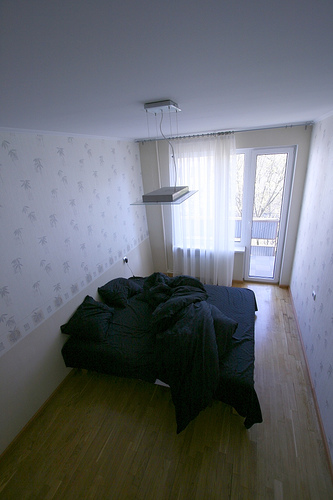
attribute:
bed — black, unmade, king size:
[62, 276, 263, 428]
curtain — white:
[168, 131, 236, 288]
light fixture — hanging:
[130, 98, 199, 206]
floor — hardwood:
[1, 272, 333, 499]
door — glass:
[243, 147, 295, 284]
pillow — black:
[60, 296, 117, 340]